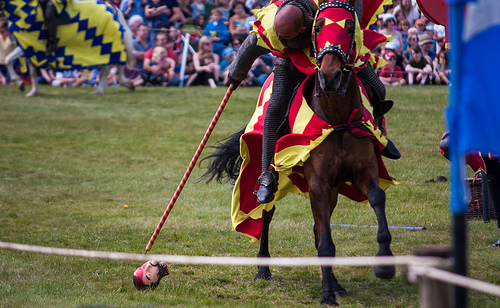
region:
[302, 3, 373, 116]
the horse is wearing a mask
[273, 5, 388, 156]
the horse is wearing a mask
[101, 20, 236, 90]
people sitting on the grass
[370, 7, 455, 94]
people sitting on the grass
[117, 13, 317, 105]
people sitting on the grass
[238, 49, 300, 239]
the legging is black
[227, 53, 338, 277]
the legging is black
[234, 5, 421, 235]
man riding a horse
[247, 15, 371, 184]
man riding a horse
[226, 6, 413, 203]
Knight wearing red and yellow armor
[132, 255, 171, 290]
fake head on ground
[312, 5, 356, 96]
Horse wearing red and yellow mask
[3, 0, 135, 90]
Blue and yellow drape on horse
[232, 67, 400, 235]
red and yellow drape on horse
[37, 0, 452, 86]
spectators at a jousting event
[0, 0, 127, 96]
a white horse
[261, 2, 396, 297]
a brown horse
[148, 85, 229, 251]
a red and yellow spear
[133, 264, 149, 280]
fake blood on head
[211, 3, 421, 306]
A man on a horse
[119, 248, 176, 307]
A fake man's head on the ground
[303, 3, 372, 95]
Horse is looking at the camera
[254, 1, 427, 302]
The horse is dark brown in color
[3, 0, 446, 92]
A crowd of people in the background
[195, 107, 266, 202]
Horse's tail is black in color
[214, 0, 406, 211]
Man is wearing gray armor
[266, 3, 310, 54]
Man has a shaved head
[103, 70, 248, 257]
Man is holding a striped colored pole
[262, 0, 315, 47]
Man has his head down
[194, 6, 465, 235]
a man on a horse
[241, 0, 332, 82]
the head of a man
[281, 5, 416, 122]
the head of a horse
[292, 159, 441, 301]
the front legs of a hoese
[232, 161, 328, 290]
the hind leg of a horse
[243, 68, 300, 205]
the leg of a man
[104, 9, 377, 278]
a man with a stick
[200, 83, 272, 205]
the tail of a horse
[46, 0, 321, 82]
people in the background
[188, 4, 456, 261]
a man rind on the back of a horse